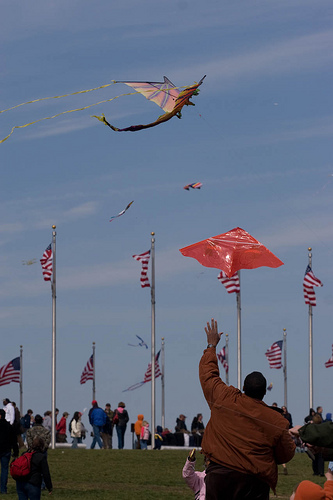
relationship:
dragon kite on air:
[0, 74, 207, 146] [0, 0, 326, 252]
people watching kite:
[5, 312, 331, 491] [126, 331, 149, 349]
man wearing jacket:
[198, 317, 297, 498] [198, 344, 295, 490]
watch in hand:
[203, 340, 219, 349] [201, 316, 224, 345]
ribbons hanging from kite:
[3, 68, 133, 136] [100, 63, 218, 144]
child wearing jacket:
[173, 454, 223, 499] [182, 463, 207, 491]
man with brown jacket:
[198, 317, 297, 498] [198, 345, 297, 494]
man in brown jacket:
[198, 317, 297, 498] [194, 345, 297, 494]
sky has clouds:
[0, 2, 332, 454] [2, 1, 331, 451]